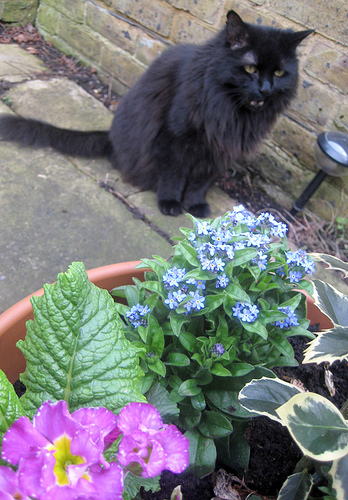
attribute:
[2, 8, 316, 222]
cat — black, sitting, long haired, scary, b;ack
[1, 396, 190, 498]
flowers — purple, pink, yellow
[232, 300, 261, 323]
flowers — blue, yellow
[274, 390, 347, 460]
leaf — white, green, large, big, mixed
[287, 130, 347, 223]
light — outdoors, solar, yard, stick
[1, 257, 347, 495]
pot — full, sitting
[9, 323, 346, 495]
soil — dark, brown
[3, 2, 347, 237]
wall — brick, light, tan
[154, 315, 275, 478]
plant — dark, green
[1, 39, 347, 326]
patio — brick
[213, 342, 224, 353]
flower — small, b;ue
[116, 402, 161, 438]
flower — purple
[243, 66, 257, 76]
eye — green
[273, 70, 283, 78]
eye — green